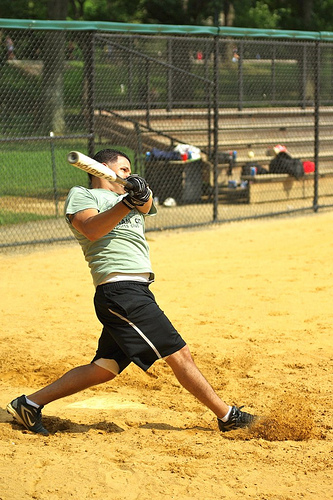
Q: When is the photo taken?
A: Daytime.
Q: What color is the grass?
A: Green.